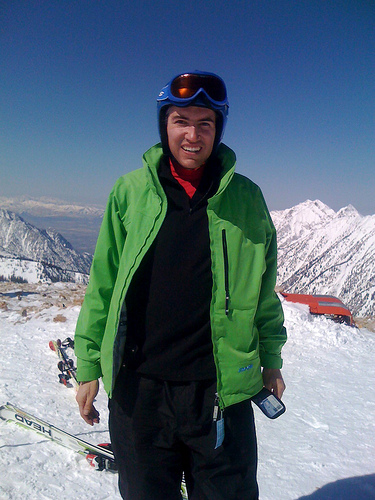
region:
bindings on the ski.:
[86, 453, 109, 470]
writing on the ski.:
[14, 412, 52, 437]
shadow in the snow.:
[335, 483, 364, 493]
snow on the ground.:
[318, 398, 357, 428]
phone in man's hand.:
[251, 391, 284, 424]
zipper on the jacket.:
[210, 395, 222, 421]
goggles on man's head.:
[168, 72, 227, 101]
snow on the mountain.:
[293, 211, 309, 235]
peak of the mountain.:
[303, 195, 321, 206]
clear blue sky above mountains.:
[66, 67, 106, 92]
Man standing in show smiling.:
[0, 68, 374, 497]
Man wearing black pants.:
[73, 67, 292, 499]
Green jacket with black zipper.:
[71, 138, 287, 448]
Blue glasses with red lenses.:
[153, 66, 245, 115]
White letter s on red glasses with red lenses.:
[154, 70, 232, 109]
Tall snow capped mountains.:
[0, 189, 373, 326]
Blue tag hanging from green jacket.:
[70, 138, 290, 432]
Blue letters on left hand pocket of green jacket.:
[73, 69, 292, 407]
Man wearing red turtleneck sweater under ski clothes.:
[70, 68, 290, 497]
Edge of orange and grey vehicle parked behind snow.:
[1, 286, 371, 497]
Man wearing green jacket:
[72, 68, 298, 314]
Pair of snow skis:
[4, 396, 118, 476]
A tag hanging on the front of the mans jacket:
[182, 362, 250, 464]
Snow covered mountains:
[276, 176, 374, 282]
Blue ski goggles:
[138, 61, 248, 141]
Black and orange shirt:
[150, 156, 242, 275]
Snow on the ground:
[291, 325, 364, 417]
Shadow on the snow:
[276, 450, 373, 498]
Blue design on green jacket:
[224, 347, 265, 386]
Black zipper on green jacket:
[213, 220, 249, 328]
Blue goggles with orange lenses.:
[153, 67, 232, 110]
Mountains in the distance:
[0, 203, 85, 281]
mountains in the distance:
[270, 200, 372, 309]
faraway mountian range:
[1, 192, 100, 220]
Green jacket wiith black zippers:
[75, 133, 290, 411]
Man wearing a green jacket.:
[65, 63, 290, 499]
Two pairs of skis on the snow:
[0, 303, 221, 498]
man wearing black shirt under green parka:
[63, 62, 296, 497]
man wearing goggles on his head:
[65, 63, 290, 498]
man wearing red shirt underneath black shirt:
[69, 67, 289, 499]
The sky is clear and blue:
[18, 18, 140, 108]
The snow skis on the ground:
[2, 397, 115, 480]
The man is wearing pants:
[101, 370, 261, 498]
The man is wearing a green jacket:
[68, 149, 295, 413]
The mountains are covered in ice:
[288, 195, 369, 274]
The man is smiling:
[174, 141, 208, 159]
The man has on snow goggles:
[145, 72, 239, 113]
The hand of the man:
[66, 375, 109, 426]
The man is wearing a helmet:
[145, 69, 230, 162]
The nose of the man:
[185, 123, 202, 142]